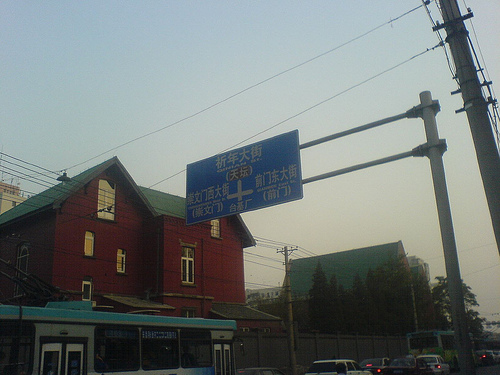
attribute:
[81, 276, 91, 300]
window — small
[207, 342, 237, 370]
windows — small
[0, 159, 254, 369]
building — large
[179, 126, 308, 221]
street sign — blue and white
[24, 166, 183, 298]
building — red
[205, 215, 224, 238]
window — small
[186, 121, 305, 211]
street sign — blue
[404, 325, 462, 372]
bus — yellow, white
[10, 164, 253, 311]
house — red, large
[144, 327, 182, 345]
sign — blue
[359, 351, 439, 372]
car — red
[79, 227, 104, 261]
window — small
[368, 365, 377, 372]
light — red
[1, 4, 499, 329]
sky — blue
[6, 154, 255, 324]
house — brown, green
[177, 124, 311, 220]
sign — blue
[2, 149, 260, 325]
building — red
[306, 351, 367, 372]
car — white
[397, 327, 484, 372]
bus — white, green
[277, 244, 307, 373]
power line — brown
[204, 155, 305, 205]
chinese writing — Chinese 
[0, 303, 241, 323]
roof — light blue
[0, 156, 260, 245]
roof — green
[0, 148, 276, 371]
building — red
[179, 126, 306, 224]
traffic sign — blue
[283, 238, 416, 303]
roof — green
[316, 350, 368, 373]
suv — white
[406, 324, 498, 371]
bus — blue, green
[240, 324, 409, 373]
fence — long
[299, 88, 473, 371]
post — metal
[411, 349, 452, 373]
hatchback — white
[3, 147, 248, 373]
building — large